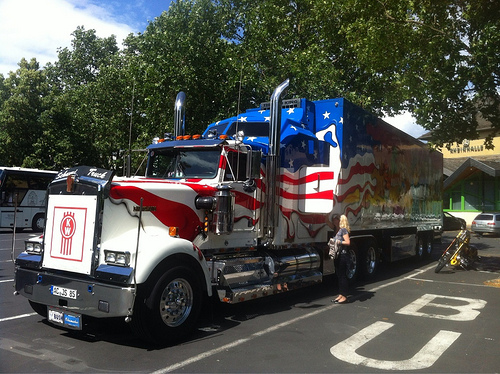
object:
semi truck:
[12, 76, 442, 346]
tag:
[49, 283, 77, 300]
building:
[418, 92, 500, 231]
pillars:
[447, 184, 464, 212]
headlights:
[104, 250, 133, 266]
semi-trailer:
[10, 78, 445, 340]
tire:
[434, 255, 452, 273]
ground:
[0, 261, 500, 374]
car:
[403, 226, 432, 249]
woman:
[328, 208, 352, 307]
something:
[327, 238, 342, 260]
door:
[220, 145, 257, 241]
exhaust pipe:
[264, 77, 291, 244]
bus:
[0, 166, 79, 234]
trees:
[222, 5, 483, 153]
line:
[206, 315, 285, 354]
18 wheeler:
[10, 75, 445, 341]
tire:
[137, 261, 206, 346]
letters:
[327, 292, 488, 374]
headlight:
[25, 241, 45, 254]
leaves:
[0, 0, 500, 168]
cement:
[258, 295, 500, 374]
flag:
[49, 205, 90, 264]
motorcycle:
[434, 213, 483, 273]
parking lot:
[0, 251, 497, 371]